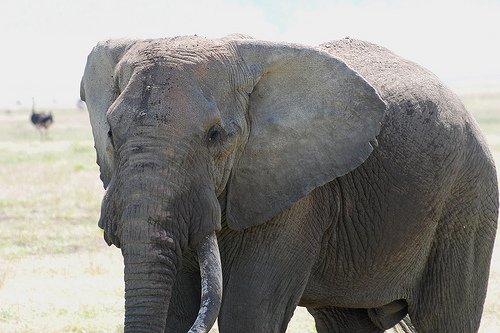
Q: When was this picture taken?
A: During the day.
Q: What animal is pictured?
A: An elephant.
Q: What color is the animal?
A: Gray.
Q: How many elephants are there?
A: One.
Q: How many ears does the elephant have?
A: Two.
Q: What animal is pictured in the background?
A: An ostrich.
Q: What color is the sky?
A: Gray.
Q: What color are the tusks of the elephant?
A: White.